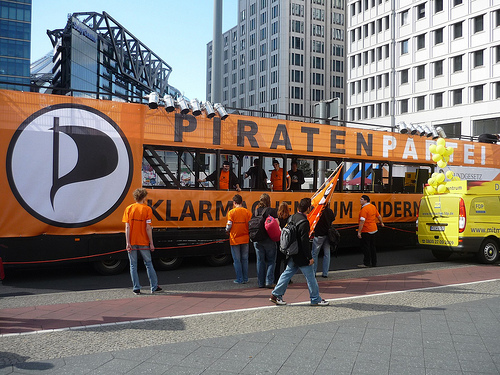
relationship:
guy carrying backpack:
[268, 191, 339, 318] [272, 222, 300, 259]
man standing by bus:
[122, 195, 164, 297] [2, 87, 499, 269]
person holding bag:
[248, 194, 282, 288] [266, 215, 281, 240]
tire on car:
[479, 240, 499, 267] [412, 164, 499, 260]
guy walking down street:
[269, 198, 328, 306] [1, 251, 496, 323]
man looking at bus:
[122, 188, 164, 295] [1, 93, 499, 254]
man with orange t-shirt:
[122, 188, 164, 295] [112, 204, 166, 246]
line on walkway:
[144, 307, 208, 324] [3, 262, 499, 371]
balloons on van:
[427, 137, 454, 168] [415, 173, 498, 265]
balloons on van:
[426, 171, 447, 193] [415, 173, 498, 265]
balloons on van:
[447, 170, 462, 181] [415, 173, 498, 265]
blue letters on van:
[470, 197, 492, 220] [417, 176, 499, 273]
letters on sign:
[169, 111, 374, 162] [1, 77, 499, 246]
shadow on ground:
[1, 267, 498, 369] [1, 259, 499, 373]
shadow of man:
[1, 267, 498, 369] [122, 188, 164, 295]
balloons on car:
[419, 130, 464, 209] [412, 164, 499, 260]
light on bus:
[148, 89, 158, 110] [2, 87, 499, 269]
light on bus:
[162, 91, 176, 111] [2, 87, 499, 269]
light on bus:
[177, 95, 191, 115] [2, 87, 499, 269]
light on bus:
[188, 97, 202, 116] [2, 87, 499, 269]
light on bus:
[203, 100, 217, 117] [2, 87, 499, 269]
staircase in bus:
[139, 145, 182, 188] [2, 87, 499, 269]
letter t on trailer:
[299, 126, 320, 149] [106, 62, 300, 248]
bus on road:
[2, 87, 499, 269] [1, 261, 499, 373]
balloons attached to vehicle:
[425, 138, 460, 194] [411, 197, 474, 249]